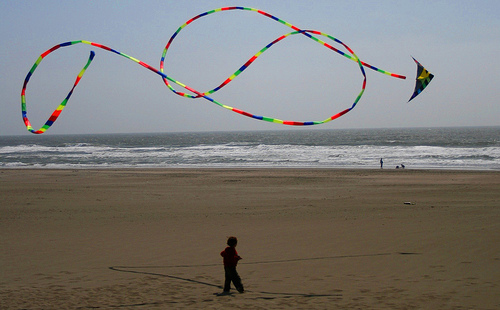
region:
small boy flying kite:
[209, 231, 249, 301]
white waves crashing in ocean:
[42, 146, 419, 173]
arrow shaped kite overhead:
[410, 50, 440, 105]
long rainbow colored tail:
[29, 21, 394, 152]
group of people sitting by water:
[379, 157, 419, 177]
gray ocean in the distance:
[42, 117, 489, 172]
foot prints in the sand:
[65, 263, 267, 306]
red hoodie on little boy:
[212, 250, 254, 282]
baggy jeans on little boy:
[220, 267, 260, 290]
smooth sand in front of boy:
[65, 176, 490, 279]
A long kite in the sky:
[20, 5, 434, 135]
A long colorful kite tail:
[20, 3, 406, 134]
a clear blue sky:
[0, 0, 499, 135]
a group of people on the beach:
[378, 155, 410, 168]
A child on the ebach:
[216, 235, 245, 294]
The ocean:
[2, 124, 498, 171]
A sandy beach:
[2, 168, 498, 308]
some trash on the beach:
[402, 198, 415, 207]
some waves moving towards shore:
[0, 143, 499, 167]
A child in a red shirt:
[218, 236, 243, 293]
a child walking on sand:
[156, 223, 375, 299]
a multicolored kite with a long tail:
[13, 15, 446, 135]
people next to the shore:
[359, 147, 436, 178]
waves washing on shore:
[6, 135, 492, 191]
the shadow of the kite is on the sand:
[105, 241, 425, 303]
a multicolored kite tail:
[21, 3, 411, 163]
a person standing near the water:
[361, 143, 390, 173]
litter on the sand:
[388, 189, 452, 224]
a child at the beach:
[181, 131, 288, 304]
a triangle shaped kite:
[406, 48, 440, 117]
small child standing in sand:
[220, 232, 244, 296]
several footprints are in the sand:
[8, 273, 165, 305]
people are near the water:
[376, 155, 408, 172]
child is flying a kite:
[18, 5, 435, 295]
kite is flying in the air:
[20, 5, 435, 139]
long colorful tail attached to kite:
[18, 5, 408, 134]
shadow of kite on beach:
[103, 247, 425, 304]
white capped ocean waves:
[5, 138, 493, 160]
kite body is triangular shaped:
[407, 55, 435, 106]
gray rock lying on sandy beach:
[398, 197, 415, 207]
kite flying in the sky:
[16, 13, 441, 147]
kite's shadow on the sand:
[103, 222, 430, 294]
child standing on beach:
[215, 234, 243, 287]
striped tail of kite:
[2, 5, 409, 155]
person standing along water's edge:
[372, 157, 388, 164]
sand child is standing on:
[3, 173, 483, 307]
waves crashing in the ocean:
[13, 131, 498, 171]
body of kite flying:
[406, 53, 436, 107]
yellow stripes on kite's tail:
[12, 7, 409, 152]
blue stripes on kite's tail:
[11, 2, 407, 166]